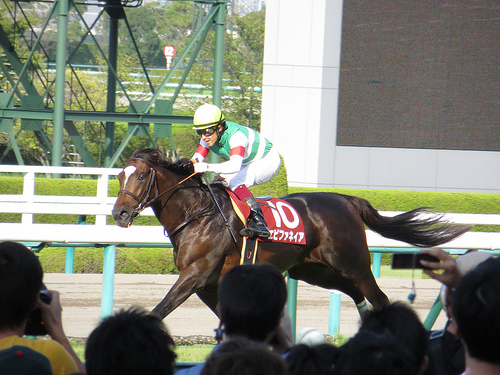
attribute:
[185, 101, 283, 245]
jockey — leaning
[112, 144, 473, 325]
horse — running, brown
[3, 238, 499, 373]
crowd — people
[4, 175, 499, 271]
grass — green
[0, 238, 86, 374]
man — videoing, photographer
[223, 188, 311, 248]
blanket — numbered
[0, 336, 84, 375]
shirt — yellow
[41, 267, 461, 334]
track — gravel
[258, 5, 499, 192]
wall — concrete